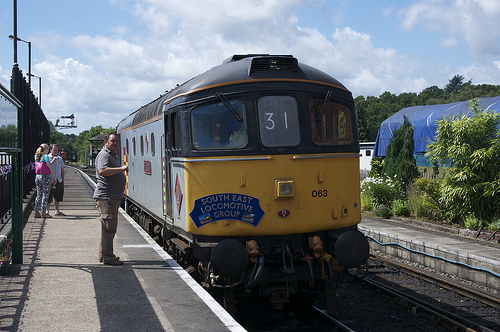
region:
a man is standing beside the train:
[76, 41, 397, 318]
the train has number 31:
[103, 49, 393, 311]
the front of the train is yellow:
[153, 53, 395, 295]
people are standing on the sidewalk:
[31, 122, 98, 232]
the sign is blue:
[189, 183, 272, 251]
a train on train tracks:
[86, 50, 440, 330]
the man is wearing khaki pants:
[79, 121, 156, 282]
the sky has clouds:
[6, 2, 494, 151]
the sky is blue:
[2, 2, 499, 134]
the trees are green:
[352, 79, 497, 239]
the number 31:
[261, 107, 293, 137]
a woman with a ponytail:
[32, 140, 50, 161]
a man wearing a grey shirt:
[94, 127, 130, 266]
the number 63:
[307, 186, 332, 198]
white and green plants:
[360, 170, 405, 205]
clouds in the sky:
[40, 22, 129, 99]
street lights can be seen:
[6, 29, 46, 103]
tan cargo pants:
[92, 192, 122, 255]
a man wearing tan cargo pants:
[91, 130, 130, 267]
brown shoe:
[98, 251, 125, 267]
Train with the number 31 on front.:
[112, 49, 372, 296]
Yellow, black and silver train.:
[115, 50, 372, 295]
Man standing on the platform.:
[91, 123, 130, 264]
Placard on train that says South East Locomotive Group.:
[187, 186, 267, 229]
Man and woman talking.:
[32, 139, 67, 219]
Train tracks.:
[356, 245, 496, 330]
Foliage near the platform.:
[362, 109, 499, 232]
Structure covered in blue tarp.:
[370, 96, 498, 166]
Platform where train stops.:
[0, 157, 245, 329]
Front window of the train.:
[186, 84, 253, 151]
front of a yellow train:
[160, 49, 392, 276]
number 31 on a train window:
[262, 106, 296, 138]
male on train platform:
[88, 129, 135, 271]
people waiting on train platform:
[25, 133, 69, 219]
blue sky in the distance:
[14, 4, 122, 27]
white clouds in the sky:
[56, 31, 152, 92]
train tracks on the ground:
[267, 278, 482, 329]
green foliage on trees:
[383, 125, 498, 201]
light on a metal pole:
[7, 32, 39, 79]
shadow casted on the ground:
[38, 264, 168, 330]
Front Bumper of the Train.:
[205, 231, 363, 281]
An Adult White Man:
[87, 130, 130, 265]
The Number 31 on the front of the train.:
[250, 95, 303, 146]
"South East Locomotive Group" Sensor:
[185, 190, 266, 225]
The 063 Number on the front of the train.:
[305, 183, 336, 206]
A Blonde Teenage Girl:
[30, 141, 53, 231]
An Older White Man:
[45, 138, 65, 220]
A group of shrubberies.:
[385, 117, 498, 235]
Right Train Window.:
[187, 105, 247, 150]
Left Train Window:
[305, 94, 356, 149]